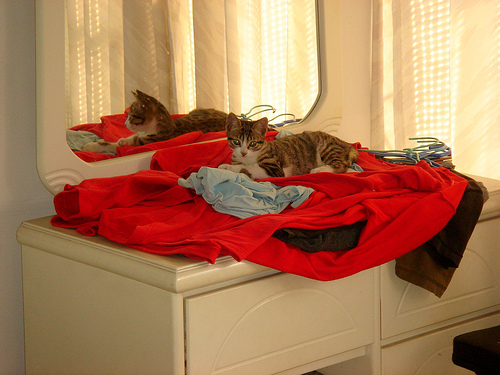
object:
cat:
[217, 111, 360, 180]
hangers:
[356, 137, 438, 163]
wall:
[0, 0, 57, 375]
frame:
[35, 0, 346, 195]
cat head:
[225, 111, 269, 159]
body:
[218, 130, 358, 179]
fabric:
[50, 129, 472, 280]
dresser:
[15, 170, 499, 375]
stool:
[450, 322, 500, 375]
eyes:
[249, 141, 257, 148]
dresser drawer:
[378, 213, 499, 341]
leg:
[234, 158, 285, 180]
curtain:
[370, 0, 499, 182]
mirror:
[63, 0, 320, 163]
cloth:
[176, 165, 317, 219]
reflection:
[64, 0, 318, 163]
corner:
[161, 260, 196, 295]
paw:
[218, 164, 237, 173]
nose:
[241, 152, 248, 156]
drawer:
[182, 269, 377, 375]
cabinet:
[12, 171, 500, 375]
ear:
[225, 112, 238, 129]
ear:
[250, 117, 270, 133]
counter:
[13, 170, 500, 295]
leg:
[318, 154, 353, 173]